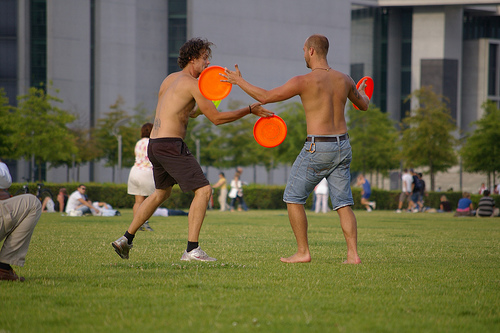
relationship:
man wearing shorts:
[217, 32, 374, 267] [277, 137, 357, 217]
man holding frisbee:
[217, 32, 374, 267] [198, 66, 234, 98]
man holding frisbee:
[217, 32, 374, 267] [351, 74, 373, 108]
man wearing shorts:
[108, 36, 276, 264] [143, 130, 210, 199]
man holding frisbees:
[217, 32, 374, 267] [346, 74, 378, 112]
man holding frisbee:
[108, 36, 276, 264] [194, 63, 233, 103]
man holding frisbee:
[108, 36, 276, 264] [249, 111, 291, 151]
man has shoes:
[108, 36, 276, 264] [182, 235, 215, 263]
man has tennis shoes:
[108, 36, 276, 264] [108, 235, 137, 262]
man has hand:
[108, 36, 276, 264] [238, 102, 283, 127]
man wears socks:
[108, 36, 276, 264] [122, 229, 197, 251]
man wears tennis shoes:
[96, 26, 267, 270] [82, 220, 209, 278]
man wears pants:
[108, 36, 276, 264] [1, 188, 47, 283]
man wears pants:
[217, 32, 374, 267] [1, 188, 47, 283]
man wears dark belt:
[217, 32, 374, 267] [303, 130, 350, 146]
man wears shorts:
[213, 32, 370, 267] [280, 127, 357, 212]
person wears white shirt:
[391, 166, 418, 214] [402, 172, 414, 193]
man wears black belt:
[217, 32, 374, 267] [301, 122, 351, 147]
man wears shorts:
[217, 32, 374, 267] [140, 132, 217, 195]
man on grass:
[62, 182, 115, 219] [47, 214, 123, 233]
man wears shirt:
[62, 182, 115, 219] [64, 190, 86, 209]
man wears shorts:
[108, 36, 276, 264] [144, 135, 214, 195]